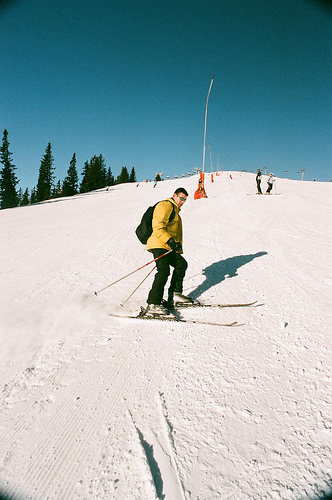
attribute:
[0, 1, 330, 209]
sky — dark blue, cloudless, blue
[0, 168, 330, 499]
snow — white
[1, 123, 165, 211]
trees — green, grouped together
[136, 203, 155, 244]
backpack — black, large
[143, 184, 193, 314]
skier — skiing, male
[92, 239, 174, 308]
ski poles — white, red, thin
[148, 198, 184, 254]
jacket — yellow, gold colored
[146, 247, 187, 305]
pants — black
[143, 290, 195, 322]
boots — black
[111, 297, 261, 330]
pair of skis — black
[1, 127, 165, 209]
leaves — green